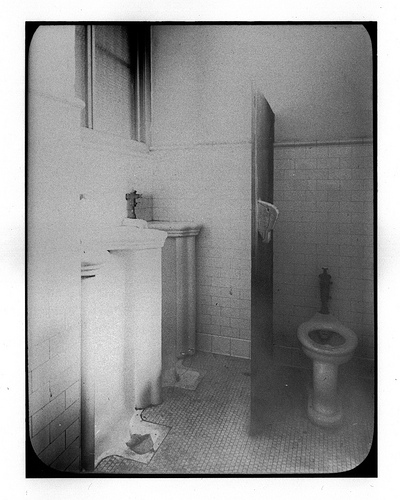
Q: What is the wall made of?
A: Brick.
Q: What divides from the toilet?
A: Privacy divider.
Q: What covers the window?
A: Blinds.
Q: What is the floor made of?
A: Tile.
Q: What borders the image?
A: Black border.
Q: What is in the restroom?
A: Toilet.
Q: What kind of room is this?
A: A bathroom.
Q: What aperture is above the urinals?
A: A window.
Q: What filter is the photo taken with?
A: Monochrome.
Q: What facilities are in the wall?
A: Urinals.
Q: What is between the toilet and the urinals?
A: A dividing wall.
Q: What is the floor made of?
A: Tiles.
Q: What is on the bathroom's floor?
A: Dirt.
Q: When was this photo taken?
A: Night.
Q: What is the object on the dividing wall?
A: A toilet paper dispenser.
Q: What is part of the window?
A: A pane.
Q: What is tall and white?
A: A toilet.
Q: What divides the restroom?
A: A wall.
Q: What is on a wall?
A: Toilets.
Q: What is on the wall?
A: A window.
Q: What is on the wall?
A: White tiles.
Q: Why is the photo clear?
A: Its during the day.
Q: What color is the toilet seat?
A: White.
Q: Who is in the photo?
A: Nobody.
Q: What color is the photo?
A: Colorless.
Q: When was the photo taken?
A: Daytime.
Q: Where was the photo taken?
A: In a public bathroom.